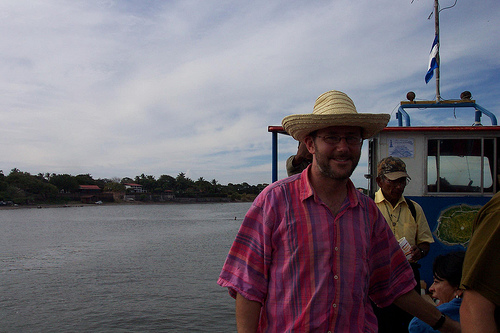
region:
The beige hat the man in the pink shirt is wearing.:
[282, 93, 392, 142]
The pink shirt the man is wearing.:
[220, 178, 415, 331]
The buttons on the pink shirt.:
[330, 215, 338, 326]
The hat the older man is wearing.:
[370, 155, 414, 187]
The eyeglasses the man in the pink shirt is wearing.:
[310, 128, 364, 147]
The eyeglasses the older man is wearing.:
[385, 180, 408, 186]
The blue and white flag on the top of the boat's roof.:
[424, 34, 446, 96]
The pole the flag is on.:
[427, 1, 446, 101]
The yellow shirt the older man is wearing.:
[375, 191, 432, 257]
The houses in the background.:
[50, 166, 172, 204]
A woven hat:
[322, 97, 344, 111]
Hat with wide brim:
[297, 119, 382, 121]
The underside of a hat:
[300, 117, 377, 122]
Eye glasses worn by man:
[325, 134, 360, 141]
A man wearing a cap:
[384, 162, 401, 173]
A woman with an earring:
[455, 295, 458, 297]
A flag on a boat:
[428, 65, 432, 73]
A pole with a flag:
[436, 68, 438, 98]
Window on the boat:
[447, 157, 477, 174]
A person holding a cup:
[400, 241, 407, 245]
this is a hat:
[273, 108, 368, 118]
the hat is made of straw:
[248, 75, 469, 205]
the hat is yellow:
[250, 81, 356, 151]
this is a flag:
[380, 21, 482, 113]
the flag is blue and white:
[424, 18, 465, 87]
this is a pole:
[352, 51, 481, 102]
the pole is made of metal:
[398, 32, 498, 149]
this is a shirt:
[215, 220, 380, 245]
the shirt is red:
[278, 237, 317, 314]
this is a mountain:
[70, 183, 134, 190]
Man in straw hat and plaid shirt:
[213, 93, 456, 331]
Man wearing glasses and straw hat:
[282, 88, 395, 198]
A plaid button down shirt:
[214, 178, 421, 326]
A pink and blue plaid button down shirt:
[214, 171, 426, 328]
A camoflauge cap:
[370, 151, 411, 178]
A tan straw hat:
[274, 86, 389, 139]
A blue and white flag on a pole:
[420, 3, 453, 99]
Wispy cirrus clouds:
[126, 131, 268, 168]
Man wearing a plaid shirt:
[215, 86, 432, 330]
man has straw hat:
[290, 77, 368, 129]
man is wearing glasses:
[315, 127, 367, 141]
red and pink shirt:
[245, 185, 404, 331]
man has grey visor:
[370, 159, 408, 185]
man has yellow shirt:
[375, 187, 409, 247]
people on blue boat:
[281, 117, 496, 329]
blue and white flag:
[418, 31, 450, 80]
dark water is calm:
[101, 220, 211, 302]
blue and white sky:
[71, 24, 438, 101]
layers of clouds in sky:
[46, 26, 436, 101]